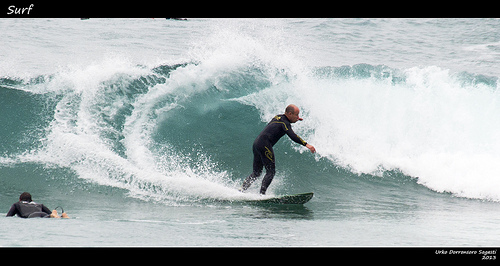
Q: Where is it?
A: This is at the ocean.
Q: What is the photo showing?
A: It is showing an ocean.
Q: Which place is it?
A: It is an ocean.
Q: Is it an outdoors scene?
A: Yes, it is outdoors.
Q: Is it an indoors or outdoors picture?
A: It is outdoors.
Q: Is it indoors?
A: No, it is outdoors.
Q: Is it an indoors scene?
A: No, it is outdoors.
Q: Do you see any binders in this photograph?
A: No, there are no binders.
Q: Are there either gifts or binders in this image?
A: No, there are no binders or gifts.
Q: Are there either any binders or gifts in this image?
A: No, there are no binders or gifts.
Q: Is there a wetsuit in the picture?
A: Yes, there is a wetsuit.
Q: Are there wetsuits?
A: Yes, there is a wetsuit.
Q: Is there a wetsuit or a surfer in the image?
A: Yes, there is a wetsuit.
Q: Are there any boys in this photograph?
A: No, there are no boys.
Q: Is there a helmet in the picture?
A: No, there are no helmets.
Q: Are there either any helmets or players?
A: No, there are no helmets or players.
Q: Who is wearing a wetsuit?
A: The man is wearing a wetsuit.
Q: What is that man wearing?
A: The man is wearing a wetsuit.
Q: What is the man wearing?
A: The man is wearing a wetsuit.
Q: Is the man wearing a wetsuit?
A: Yes, the man is wearing a wetsuit.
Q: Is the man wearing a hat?
A: No, the man is wearing a wetsuit.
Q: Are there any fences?
A: No, there are no fences.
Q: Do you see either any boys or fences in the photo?
A: No, there are no fences or boys.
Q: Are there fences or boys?
A: No, there are no fences or boys.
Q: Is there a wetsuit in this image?
A: Yes, there is a wetsuit.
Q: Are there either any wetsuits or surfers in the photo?
A: Yes, there is a wetsuit.